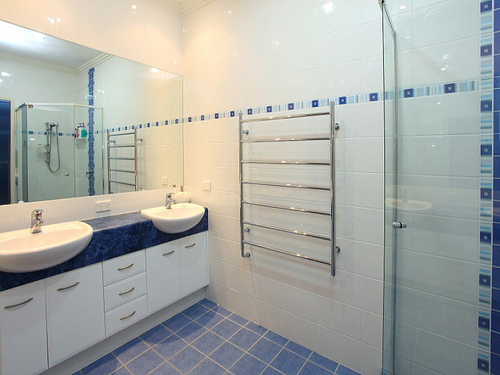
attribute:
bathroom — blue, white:
[1, 0, 498, 375]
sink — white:
[142, 201, 205, 232]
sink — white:
[1, 221, 94, 272]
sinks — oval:
[0, 201, 205, 272]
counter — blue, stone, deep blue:
[1, 204, 209, 296]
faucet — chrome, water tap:
[165, 191, 177, 210]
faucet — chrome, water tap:
[27, 206, 46, 235]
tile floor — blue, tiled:
[67, 297, 375, 374]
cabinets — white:
[1, 231, 208, 374]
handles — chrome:
[4, 241, 196, 320]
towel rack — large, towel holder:
[235, 100, 341, 278]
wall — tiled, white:
[183, 0, 499, 373]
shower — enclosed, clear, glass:
[379, 1, 498, 374]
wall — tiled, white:
[0, 0, 182, 81]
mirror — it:
[0, 20, 184, 208]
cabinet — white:
[146, 231, 208, 316]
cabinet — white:
[2, 262, 106, 371]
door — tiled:
[0, 100, 11, 205]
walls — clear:
[382, 2, 499, 373]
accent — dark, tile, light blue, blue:
[181, 77, 478, 125]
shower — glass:
[15, 102, 105, 200]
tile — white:
[254, 274, 282, 310]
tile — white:
[283, 283, 313, 321]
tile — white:
[333, 300, 361, 339]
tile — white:
[334, 267, 362, 308]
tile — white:
[209, 258, 229, 288]